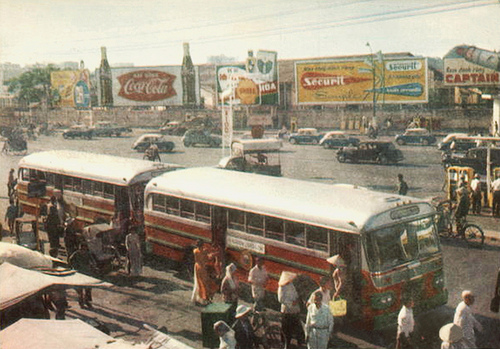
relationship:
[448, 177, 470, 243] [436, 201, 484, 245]
man sitting on bike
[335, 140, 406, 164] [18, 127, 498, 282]
car driving on street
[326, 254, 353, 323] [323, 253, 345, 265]
lady wearing a hat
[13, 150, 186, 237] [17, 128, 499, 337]
bus on a street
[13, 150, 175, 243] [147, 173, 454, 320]
bus behind a bus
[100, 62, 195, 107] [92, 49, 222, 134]
advertisement on a building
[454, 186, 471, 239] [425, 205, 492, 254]
man on a bike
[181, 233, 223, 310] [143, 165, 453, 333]
people boarding bus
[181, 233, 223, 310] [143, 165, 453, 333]
people getting off bus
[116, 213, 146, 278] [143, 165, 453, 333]
person standing near bus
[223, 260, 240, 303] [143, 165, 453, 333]
person standing near a bus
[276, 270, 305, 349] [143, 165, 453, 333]
person standing near a bus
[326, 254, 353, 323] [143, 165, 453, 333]
lady standing near bus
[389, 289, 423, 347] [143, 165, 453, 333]
person standing near bus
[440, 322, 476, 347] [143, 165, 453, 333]
person standing near bus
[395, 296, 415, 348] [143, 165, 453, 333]
person standing near bus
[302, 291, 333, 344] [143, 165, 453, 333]
person standing near bus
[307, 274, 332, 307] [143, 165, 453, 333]
person standing near bus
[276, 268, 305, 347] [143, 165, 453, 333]
person standing near bus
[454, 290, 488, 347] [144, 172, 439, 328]
person standing near bus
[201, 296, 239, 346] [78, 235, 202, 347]
trash bin on sidewalk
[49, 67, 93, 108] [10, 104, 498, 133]
billboard on road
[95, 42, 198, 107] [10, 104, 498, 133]
billboard on road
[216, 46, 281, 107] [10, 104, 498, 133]
billboard on road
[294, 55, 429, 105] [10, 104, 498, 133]
billboard on road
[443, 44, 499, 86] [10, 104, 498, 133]
billboard on road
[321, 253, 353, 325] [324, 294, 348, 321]
lady carrying purse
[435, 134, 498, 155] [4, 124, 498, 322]
car parked in parking lot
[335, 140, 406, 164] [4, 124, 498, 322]
car parked in parking lot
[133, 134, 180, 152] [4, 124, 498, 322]
car parked in parking lot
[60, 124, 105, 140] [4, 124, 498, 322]
car parked in parking lot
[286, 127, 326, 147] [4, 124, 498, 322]
car parked in parking lot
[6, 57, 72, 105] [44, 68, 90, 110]
tree by billboard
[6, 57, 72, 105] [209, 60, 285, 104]
tree by billboard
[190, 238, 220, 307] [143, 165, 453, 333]
people waiting bus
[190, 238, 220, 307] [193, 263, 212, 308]
people wearing dress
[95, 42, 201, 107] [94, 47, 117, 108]
billboard has bottle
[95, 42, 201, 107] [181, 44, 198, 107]
billboard has bottle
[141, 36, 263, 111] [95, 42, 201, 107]
bottle on right of billboard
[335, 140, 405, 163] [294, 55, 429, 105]
car under billboard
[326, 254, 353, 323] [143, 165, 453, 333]
lady coming off bus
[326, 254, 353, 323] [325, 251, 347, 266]
lady wearing hat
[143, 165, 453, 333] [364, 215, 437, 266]
bus has windshield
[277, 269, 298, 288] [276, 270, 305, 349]
hat on person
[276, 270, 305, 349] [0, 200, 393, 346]
person on sidewalk